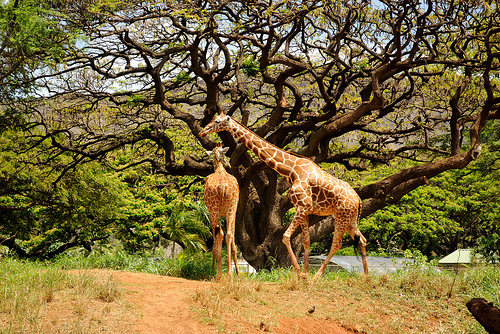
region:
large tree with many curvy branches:
[55, 5, 490, 188]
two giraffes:
[173, 100, 388, 293]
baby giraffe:
[181, 135, 270, 289]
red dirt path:
[72, 255, 227, 332]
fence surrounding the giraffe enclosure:
[208, 255, 480, 287]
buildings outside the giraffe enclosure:
[289, 230, 499, 285]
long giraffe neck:
[193, 102, 299, 184]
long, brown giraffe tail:
[350, 192, 365, 262]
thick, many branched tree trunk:
[233, 205, 312, 289]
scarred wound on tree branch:
[455, 144, 492, 172]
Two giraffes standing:
[170, 80, 401, 288]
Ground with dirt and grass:
[10, 250, 200, 320]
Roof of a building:
[335, 252, 445, 283]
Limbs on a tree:
[90, 27, 366, 103]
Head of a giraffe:
[190, 103, 237, 143]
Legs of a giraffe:
[275, 200, 395, 280]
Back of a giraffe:
[198, 167, 246, 282]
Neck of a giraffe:
[235, 133, 298, 168]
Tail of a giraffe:
[210, 183, 231, 208]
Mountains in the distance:
[21, 51, 462, 116]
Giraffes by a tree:
[159, 70, 381, 287]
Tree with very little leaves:
[90, 7, 405, 119]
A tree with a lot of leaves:
[6, 140, 119, 264]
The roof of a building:
[436, 234, 491, 272]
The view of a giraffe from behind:
[202, 148, 248, 268]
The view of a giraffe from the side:
[210, 108, 401, 264]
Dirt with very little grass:
[60, 267, 207, 329]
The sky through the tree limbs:
[85, 14, 265, 77]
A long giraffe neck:
[214, 111, 294, 184]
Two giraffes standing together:
[189, 113, 364, 271]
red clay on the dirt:
[130, 273, 178, 323]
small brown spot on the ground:
[283, 303, 334, 331]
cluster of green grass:
[18, 265, 83, 309]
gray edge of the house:
[303, 243, 392, 281]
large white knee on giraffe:
[265, 223, 308, 249]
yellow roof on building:
[433, 234, 482, 272]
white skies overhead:
[65, 59, 172, 96]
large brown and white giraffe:
[201, 104, 434, 291]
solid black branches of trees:
[110, 119, 198, 186]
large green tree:
[68, 19, 456, 243]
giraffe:
[186, 108, 386, 287]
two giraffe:
[188, 108, 377, 290]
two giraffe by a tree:
[100, 29, 400, 286]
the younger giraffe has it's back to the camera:
[195, 143, 255, 288]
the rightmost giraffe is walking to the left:
[207, 113, 383, 288]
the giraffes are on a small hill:
[182, 105, 414, 328]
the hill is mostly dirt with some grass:
[43, 237, 446, 332]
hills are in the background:
[31, 57, 498, 248]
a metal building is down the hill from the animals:
[291, 248, 455, 283]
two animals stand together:
[186, 111, 393, 281]